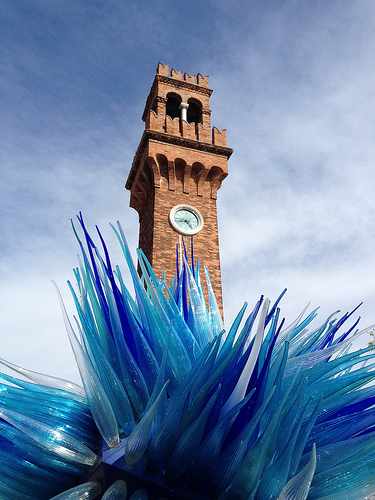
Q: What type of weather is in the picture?
A: It is cloudy.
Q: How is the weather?
A: It is cloudy.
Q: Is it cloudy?
A: Yes, it is cloudy.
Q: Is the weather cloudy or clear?
A: It is cloudy.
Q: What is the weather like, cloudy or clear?
A: It is cloudy.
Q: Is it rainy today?
A: No, it is cloudy.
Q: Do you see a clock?
A: Yes, there is a clock.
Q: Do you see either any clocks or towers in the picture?
A: Yes, there is a clock.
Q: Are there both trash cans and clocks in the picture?
A: No, there is a clock but no trash cans.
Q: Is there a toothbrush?
A: No, there are no toothbrushes.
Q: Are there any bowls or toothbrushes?
A: No, there are no toothbrushes or bowls.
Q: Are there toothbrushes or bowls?
A: No, there are no toothbrushes or bowls.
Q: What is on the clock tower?
A: The clock is on the clock tower.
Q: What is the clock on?
A: The clock is on the clock tower.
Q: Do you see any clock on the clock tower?
A: Yes, there is a clock on the clock tower.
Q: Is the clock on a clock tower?
A: Yes, the clock is on a clock tower.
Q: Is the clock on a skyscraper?
A: No, the clock is on a clock tower.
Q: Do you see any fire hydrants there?
A: No, there are no fire hydrants.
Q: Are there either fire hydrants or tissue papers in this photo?
A: No, there are no fire hydrants or tissue papers.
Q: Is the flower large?
A: Yes, the flower is large.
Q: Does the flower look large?
A: Yes, the flower is large.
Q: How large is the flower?
A: The flower is large.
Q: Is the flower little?
A: No, the flower is large.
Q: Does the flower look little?
A: No, the flower is large.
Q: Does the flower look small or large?
A: The flower is large.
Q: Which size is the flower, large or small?
A: The flower is large.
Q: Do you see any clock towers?
A: Yes, there is a clock tower.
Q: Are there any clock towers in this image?
A: Yes, there is a clock tower.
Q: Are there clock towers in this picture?
A: Yes, there is a clock tower.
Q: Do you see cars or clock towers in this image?
A: Yes, there is a clock tower.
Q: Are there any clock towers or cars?
A: Yes, there is a clock tower.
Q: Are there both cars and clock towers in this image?
A: No, there is a clock tower but no cars.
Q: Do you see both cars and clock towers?
A: No, there is a clock tower but no cars.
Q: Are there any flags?
A: No, there are no flags.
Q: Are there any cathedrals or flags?
A: No, there are no flags or cathedrals.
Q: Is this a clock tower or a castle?
A: This is a clock tower.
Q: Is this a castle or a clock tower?
A: This is a clock tower.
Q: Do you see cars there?
A: No, there are no cars.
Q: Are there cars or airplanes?
A: No, there are no cars or airplanes.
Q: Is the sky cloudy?
A: Yes, the sky is cloudy.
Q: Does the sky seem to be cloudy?
A: Yes, the sky is cloudy.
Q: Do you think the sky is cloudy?
A: Yes, the sky is cloudy.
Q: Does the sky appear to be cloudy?
A: Yes, the sky is cloudy.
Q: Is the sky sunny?
A: No, the sky is cloudy.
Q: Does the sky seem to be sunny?
A: No, the sky is cloudy.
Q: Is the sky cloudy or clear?
A: The sky is cloudy.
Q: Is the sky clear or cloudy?
A: The sky is cloudy.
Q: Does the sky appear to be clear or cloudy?
A: The sky is cloudy.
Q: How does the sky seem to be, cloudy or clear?
A: The sky is cloudy.